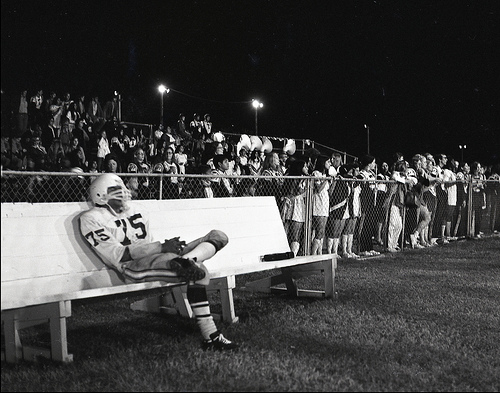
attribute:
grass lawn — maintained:
[334, 304, 441, 366]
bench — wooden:
[9, 179, 73, 351]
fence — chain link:
[2, 167, 494, 309]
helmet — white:
[74, 168, 139, 211]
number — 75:
[113, 219, 150, 241]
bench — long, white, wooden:
[1, 194, 339, 362]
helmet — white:
[88, 172, 131, 202]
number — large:
[99, 210, 154, 256]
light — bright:
[148, 78, 172, 100]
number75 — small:
[82, 224, 112, 247]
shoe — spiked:
[167, 256, 205, 283]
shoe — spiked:
[200, 330, 239, 349]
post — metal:
[301, 176, 316, 256]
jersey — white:
[76, 206, 155, 275]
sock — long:
[194, 294, 217, 333]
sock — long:
[190, 235, 226, 270]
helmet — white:
[86, 164, 136, 211]